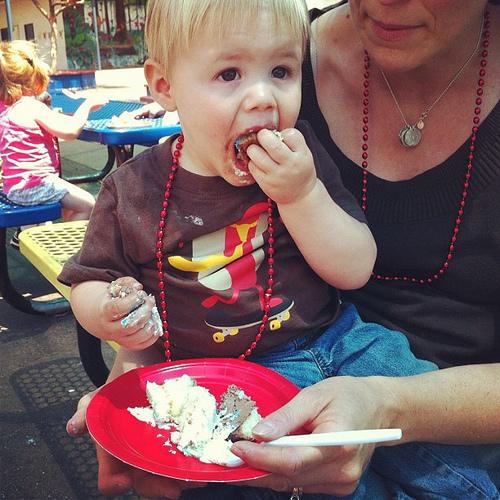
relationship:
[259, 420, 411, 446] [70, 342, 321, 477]
fork on plate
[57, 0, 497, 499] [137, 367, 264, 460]
baby eats cake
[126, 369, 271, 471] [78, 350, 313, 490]
cake on plate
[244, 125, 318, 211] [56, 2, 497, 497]
hand of child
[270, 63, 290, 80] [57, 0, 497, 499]
eye of baby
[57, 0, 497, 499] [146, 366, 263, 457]
baby eating cake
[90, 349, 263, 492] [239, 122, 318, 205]
frosting over hand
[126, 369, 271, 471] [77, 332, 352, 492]
cake on plate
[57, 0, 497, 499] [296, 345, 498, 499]
baby wearing jeans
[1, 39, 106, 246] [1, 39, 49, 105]
girl with hair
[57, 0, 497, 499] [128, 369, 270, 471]
baby eating cake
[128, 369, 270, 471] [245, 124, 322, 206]
cake with hands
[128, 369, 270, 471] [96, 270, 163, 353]
cake with hands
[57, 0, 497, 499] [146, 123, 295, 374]
baby wearing necklace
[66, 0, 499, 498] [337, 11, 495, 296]
woman wearing necklace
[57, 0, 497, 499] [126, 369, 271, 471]
baby has cake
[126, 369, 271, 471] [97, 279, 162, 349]
cake in hands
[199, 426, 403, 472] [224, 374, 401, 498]
fork in hand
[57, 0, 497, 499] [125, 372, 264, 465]
baby has frosting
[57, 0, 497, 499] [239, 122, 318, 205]
baby has hand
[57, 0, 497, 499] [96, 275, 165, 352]
baby has hand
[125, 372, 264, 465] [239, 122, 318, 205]
frosting on hand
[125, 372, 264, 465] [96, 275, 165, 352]
frosting on hand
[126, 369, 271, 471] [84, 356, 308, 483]
cake in bowl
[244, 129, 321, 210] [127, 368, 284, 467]
hand full of icecream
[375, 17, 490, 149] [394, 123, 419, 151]
locket necklace with locket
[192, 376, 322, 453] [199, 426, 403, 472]
thumb holding fork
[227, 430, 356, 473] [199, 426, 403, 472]
finger holding fork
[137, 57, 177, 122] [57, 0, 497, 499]
ear of baby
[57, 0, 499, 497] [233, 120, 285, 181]
baby eating cake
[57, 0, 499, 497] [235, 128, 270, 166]
baby eating cake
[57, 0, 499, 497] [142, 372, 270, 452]
baby eating cake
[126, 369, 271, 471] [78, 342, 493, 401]
cake on plate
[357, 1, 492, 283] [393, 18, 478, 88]
beads on neck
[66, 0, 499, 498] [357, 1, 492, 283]
woman wearing beads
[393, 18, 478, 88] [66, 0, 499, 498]
neck of woman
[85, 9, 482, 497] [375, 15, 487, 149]
woman wearing locket necklace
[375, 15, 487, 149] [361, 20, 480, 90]
locket necklace on neck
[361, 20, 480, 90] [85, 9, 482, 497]
neck of woman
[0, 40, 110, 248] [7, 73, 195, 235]
girl sitting at table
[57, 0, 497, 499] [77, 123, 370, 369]
baby wearing a shirt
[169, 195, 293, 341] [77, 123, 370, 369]
cartoon on shirt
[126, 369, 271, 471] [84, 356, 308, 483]
cake on bowl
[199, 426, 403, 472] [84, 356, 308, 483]
fork on bowl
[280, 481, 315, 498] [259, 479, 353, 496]
wedding ring on finger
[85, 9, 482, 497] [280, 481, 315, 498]
woman wearing wedding ring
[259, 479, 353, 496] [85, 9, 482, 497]
finger of woman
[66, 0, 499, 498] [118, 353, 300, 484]
woman holding plate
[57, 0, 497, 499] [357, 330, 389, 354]
baby wears jeans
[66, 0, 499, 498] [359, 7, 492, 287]
woman wearing necklace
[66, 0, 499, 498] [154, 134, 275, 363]
woman wearing necklace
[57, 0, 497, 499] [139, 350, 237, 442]
baby eating ice cream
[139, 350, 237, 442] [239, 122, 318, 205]
ice cream in hand